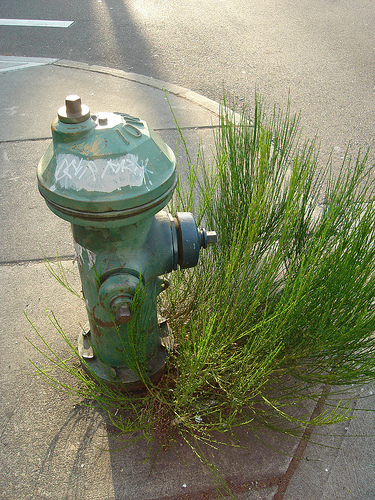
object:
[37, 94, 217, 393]
fire hydrant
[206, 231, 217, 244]
screw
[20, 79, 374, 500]
grass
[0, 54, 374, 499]
sidewalk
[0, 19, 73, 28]
line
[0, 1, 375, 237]
street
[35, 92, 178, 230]
top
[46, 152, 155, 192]
graffiti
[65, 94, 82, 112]
bolt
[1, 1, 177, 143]
shadow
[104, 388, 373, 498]
shadow